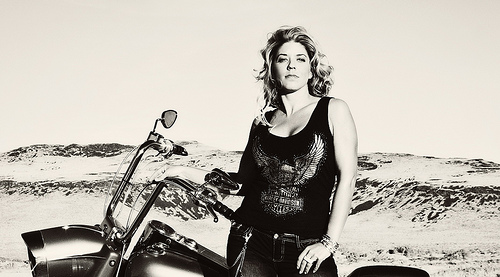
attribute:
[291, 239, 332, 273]
hand — woman's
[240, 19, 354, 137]
hair — blonde, shoulder, length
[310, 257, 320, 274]
finger — part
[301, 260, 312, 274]
finger — part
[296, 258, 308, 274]
finger — part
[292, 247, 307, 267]
finger — part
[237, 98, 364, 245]
shirt — Harley-Davidson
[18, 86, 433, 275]
motorcycle — silver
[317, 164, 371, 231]
arm — part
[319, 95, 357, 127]
shoulder — part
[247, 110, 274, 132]
shoulder — part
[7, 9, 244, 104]
sky — daytime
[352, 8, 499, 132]
sky — daytime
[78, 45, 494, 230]
woman — standing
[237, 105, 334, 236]
shirt — part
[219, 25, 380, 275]
woman — waiting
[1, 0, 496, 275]
black/white shot — black, white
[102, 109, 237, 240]
handlebars — tall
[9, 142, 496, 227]
hill — rocky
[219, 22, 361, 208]
woman — staring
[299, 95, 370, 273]
arm — muscular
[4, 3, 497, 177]
sky — pale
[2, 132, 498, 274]
terrain — uneven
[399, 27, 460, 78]
sky — clear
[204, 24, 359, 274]
woman — blonde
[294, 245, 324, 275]
fingers — blond, woman's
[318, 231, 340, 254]
wrist — woman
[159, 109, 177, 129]
mirror — motorcycle, rear, view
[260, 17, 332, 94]
hair — blonde